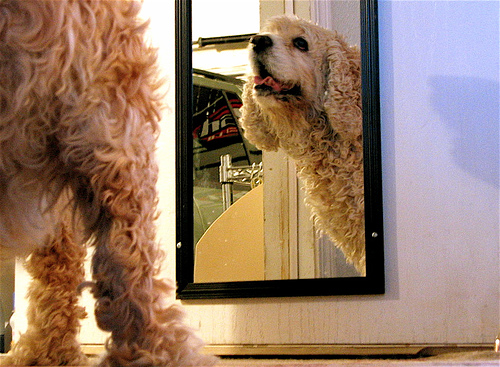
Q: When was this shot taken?
A: Daytime.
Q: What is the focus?
A: Dog in mirror.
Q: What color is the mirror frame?
A: Black.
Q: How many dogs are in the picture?
A: 1.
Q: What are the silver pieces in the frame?
A: Screws.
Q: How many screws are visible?
A: 2.